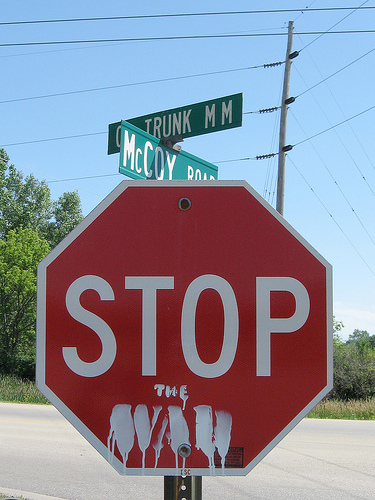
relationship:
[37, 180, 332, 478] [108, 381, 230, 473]
stop sign with graffiti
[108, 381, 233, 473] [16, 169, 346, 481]
graffiti on sign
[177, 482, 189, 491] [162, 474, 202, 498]
hole in pole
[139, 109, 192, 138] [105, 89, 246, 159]
lettering on sign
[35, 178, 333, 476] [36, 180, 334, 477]
outer edge lining sign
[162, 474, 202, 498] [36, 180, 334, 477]
pole with sign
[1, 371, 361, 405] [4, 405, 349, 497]
grass by road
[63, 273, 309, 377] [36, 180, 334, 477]
lettering on sign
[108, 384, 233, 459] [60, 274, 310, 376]
wording under stop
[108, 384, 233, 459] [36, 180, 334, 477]
wording on sign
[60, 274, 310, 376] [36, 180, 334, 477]
stop on sign